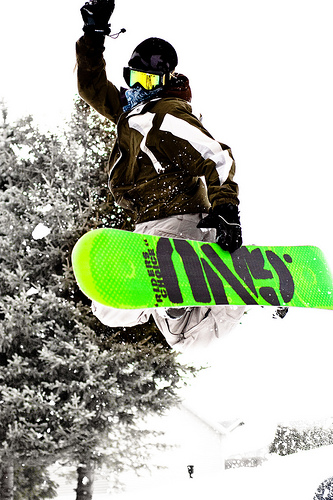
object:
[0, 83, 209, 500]
tree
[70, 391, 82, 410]
leaves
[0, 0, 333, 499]
snow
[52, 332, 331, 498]
ground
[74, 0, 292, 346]
man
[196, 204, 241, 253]
gloves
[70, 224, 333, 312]
skateboard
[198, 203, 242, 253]
hand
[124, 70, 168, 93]
goggles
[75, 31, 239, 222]
jacket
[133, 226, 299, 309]
letters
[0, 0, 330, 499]
background